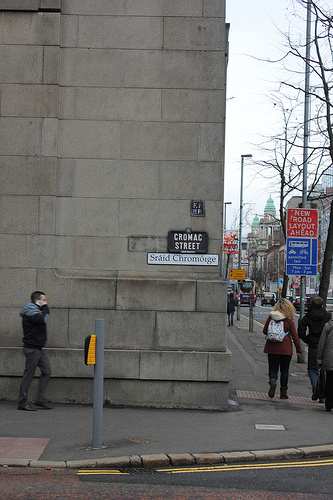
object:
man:
[17, 291, 53, 411]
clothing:
[18, 302, 52, 405]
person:
[229, 292, 235, 326]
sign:
[229, 269, 245, 279]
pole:
[236, 255, 242, 321]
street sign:
[168, 227, 207, 254]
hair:
[278, 298, 287, 309]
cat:
[263, 298, 302, 399]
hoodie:
[19, 302, 50, 349]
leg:
[38, 358, 52, 406]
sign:
[286, 238, 318, 277]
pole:
[298, 2, 311, 368]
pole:
[91, 318, 105, 451]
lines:
[75, 459, 331, 473]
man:
[297, 297, 330, 403]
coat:
[298, 309, 331, 349]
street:
[0, 299, 332, 500]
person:
[262, 297, 302, 399]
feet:
[268, 378, 277, 397]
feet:
[280, 386, 289, 399]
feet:
[18, 405, 37, 411]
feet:
[35, 401, 54, 409]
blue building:
[264, 195, 276, 211]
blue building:
[251, 214, 259, 228]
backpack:
[267, 317, 290, 343]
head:
[30, 291, 47, 308]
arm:
[30, 303, 50, 325]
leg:
[18, 358, 38, 410]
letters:
[289, 209, 314, 237]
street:
[6, 436, 332, 494]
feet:
[319, 398, 325, 403]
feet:
[231, 323, 234, 326]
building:
[0, 0, 231, 417]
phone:
[36, 299, 41, 305]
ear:
[35, 299, 37, 303]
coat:
[263, 298, 302, 357]